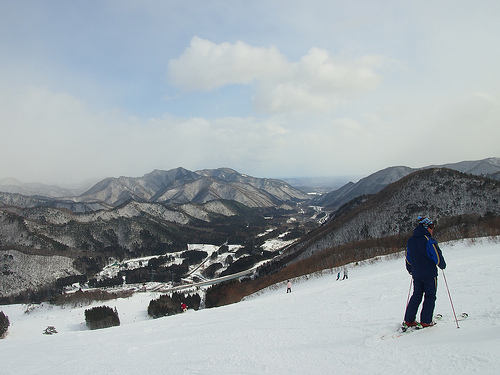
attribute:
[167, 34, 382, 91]
cloud — white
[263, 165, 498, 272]
hill — brown, grey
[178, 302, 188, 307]
jacket — red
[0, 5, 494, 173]
sky — blue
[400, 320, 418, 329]
boot — red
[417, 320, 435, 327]
boot — red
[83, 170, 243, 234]
hill — brown, grey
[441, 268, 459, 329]
ski pole — red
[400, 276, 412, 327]
ski pole — red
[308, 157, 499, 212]
hill — brown, grey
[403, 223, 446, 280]
jacket — blue, black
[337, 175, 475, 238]
hill — grey, brown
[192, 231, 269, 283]
trees — brown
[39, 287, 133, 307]
trees — brown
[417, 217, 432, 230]
knit cap — blue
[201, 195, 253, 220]
hill — brown, grey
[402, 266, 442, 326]
pants — blue, yellow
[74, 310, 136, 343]
snow — white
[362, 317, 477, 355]
snow — white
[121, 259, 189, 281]
tree — brown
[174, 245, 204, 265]
tree — brown